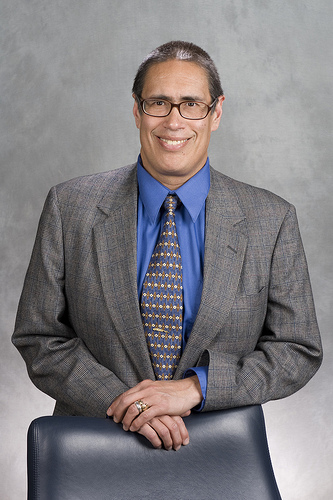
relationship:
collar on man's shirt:
[130, 157, 212, 225] [132, 157, 208, 354]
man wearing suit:
[11, 40, 322, 452] [12, 161, 323, 418]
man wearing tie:
[11, 40, 322, 452] [138, 195, 184, 383]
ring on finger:
[133, 397, 149, 412] [124, 394, 149, 422]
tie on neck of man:
[139, 188, 182, 377] [11, 40, 322, 452]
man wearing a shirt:
[11, 40, 322, 452] [131, 152, 207, 410]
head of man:
[119, 36, 227, 190] [11, 40, 322, 452]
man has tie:
[16, 34, 311, 487] [133, 195, 184, 379]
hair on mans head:
[129, 41, 223, 115] [131, 39, 224, 177]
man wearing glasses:
[11, 40, 322, 452] [132, 90, 223, 124]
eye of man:
[183, 98, 200, 106] [11, 40, 322, 452]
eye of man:
[154, 102, 165, 106] [11, 40, 322, 452]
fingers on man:
[106, 390, 154, 432] [11, 40, 322, 452]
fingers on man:
[146, 415, 189, 453] [11, 40, 322, 452]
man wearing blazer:
[11, 40, 322, 452] [6, 142, 323, 446]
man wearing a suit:
[11, 40, 322, 452] [12, 161, 323, 418]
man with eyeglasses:
[11, 40, 322, 452] [131, 89, 218, 120]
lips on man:
[131, 109, 219, 169] [71, 53, 317, 359]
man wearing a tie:
[11, 40, 322, 452] [142, 196, 182, 377]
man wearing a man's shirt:
[11, 40, 322, 452] [135, 152, 210, 412]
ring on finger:
[137, 399, 147, 410] [120, 397, 151, 430]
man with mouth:
[11, 40, 322, 452] [154, 132, 193, 150]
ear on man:
[125, 92, 144, 135] [11, 40, 322, 452]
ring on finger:
[138, 400, 148, 412] [120, 394, 157, 432]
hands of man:
[103, 377, 199, 453] [11, 40, 322, 452]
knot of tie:
[163, 192, 178, 211] [138, 195, 184, 383]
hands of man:
[103, 370, 203, 450] [11, 40, 322, 452]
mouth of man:
[149, 128, 195, 159] [61, 37, 286, 374]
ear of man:
[201, 89, 232, 137] [93, 52, 292, 306]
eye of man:
[150, 98, 166, 108] [10, 12, 332, 374]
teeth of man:
[159, 139, 187, 145] [11, 40, 322, 452]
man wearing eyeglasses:
[11, 40, 322, 452] [135, 95, 218, 120]